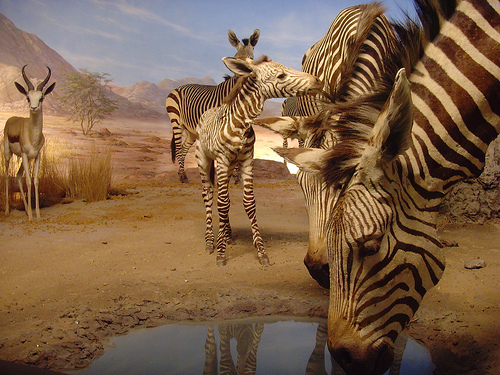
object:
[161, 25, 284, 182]
zebra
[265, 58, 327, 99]
face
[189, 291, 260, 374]
shadow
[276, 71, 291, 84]
eye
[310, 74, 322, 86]
nose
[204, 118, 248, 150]
skin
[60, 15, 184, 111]
view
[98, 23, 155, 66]
sky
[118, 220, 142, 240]
sand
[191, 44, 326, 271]
zebras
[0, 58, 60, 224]
antelope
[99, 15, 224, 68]
clouds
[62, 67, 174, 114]
range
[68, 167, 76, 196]
grass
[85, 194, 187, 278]
ground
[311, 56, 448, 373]
head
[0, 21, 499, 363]
display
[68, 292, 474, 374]
pond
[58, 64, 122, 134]
tree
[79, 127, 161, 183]
desert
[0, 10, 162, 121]
mountain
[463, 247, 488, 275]
rock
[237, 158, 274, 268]
leg